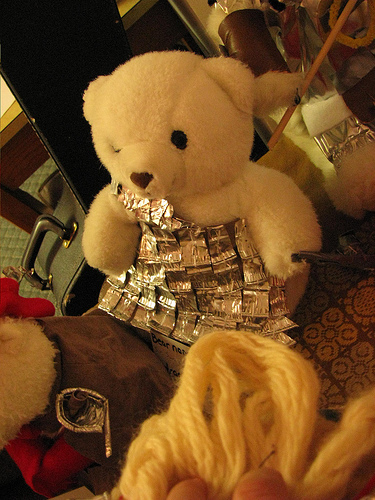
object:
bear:
[80, 47, 321, 346]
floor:
[282, 214, 373, 415]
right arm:
[80, 172, 144, 283]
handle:
[17, 213, 78, 290]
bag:
[15, 188, 101, 314]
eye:
[112, 144, 123, 154]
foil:
[96, 181, 300, 349]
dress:
[93, 184, 300, 348]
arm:
[242, 161, 324, 281]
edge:
[64, 175, 78, 196]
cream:
[235, 430, 269, 456]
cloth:
[44, 305, 175, 461]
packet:
[54, 385, 120, 463]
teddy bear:
[78, 50, 320, 385]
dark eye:
[170, 128, 187, 150]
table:
[0, 98, 47, 239]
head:
[81, 51, 253, 198]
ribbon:
[97, 317, 375, 500]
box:
[15, 178, 102, 321]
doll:
[0, 273, 56, 323]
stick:
[268, 0, 357, 144]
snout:
[129, 170, 155, 191]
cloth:
[303, 265, 369, 411]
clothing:
[89, 172, 299, 349]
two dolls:
[0, 47, 324, 495]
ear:
[201, 55, 254, 109]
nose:
[129, 169, 155, 190]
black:
[174, 130, 181, 142]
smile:
[140, 190, 153, 196]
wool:
[115, 334, 375, 500]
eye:
[171, 129, 189, 150]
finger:
[164, 477, 206, 499]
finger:
[232, 470, 289, 499]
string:
[178, 383, 205, 476]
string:
[183, 339, 211, 483]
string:
[212, 346, 246, 499]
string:
[300, 361, 315, 478]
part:
[183, 342, 197, 365]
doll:
[81, 46, 321, 314]